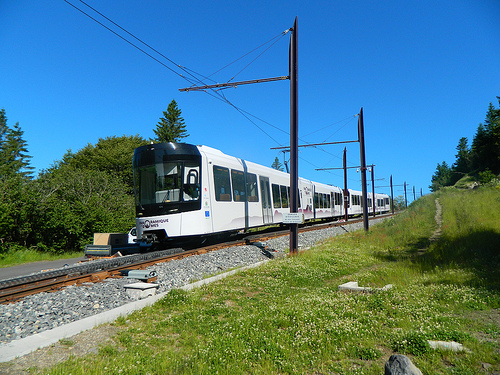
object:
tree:
[153, 98, 188, 142]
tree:
[25, 166, 132, 247]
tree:
[54, 136, 146, 183]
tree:
[0, 109, 35, 252]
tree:
[428, 161, 456, 193]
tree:
[450, 137, 477, 185]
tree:
[469, 121, 491, 173]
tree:
[482, 100, 499, 176]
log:
[378, 343, 429, 373]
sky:
[0, 0, 499, 148]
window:
[211, 160, 235, 203]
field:
[257, 232, 469, 358]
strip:
[428, 193, 449, 256]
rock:
[380, 349, 425, 374]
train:
[127, 126, 377, 258]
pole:
[286, 21, 302, 254]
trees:
[151, 99, 194, 141]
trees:
[0, 107, 130, 227]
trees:
[432, 157, 498, 179]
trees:
[458, 97, 498, 154]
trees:
[2, 221, 83, 256]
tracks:
[0, 208, 408, 306]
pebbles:
[0, 215, 397, 345]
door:
[258, 177, 273, 224]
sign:
[271, 210, 305, 228]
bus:
[127, 140, 392, 242]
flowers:
[249, 294, 396, 358]